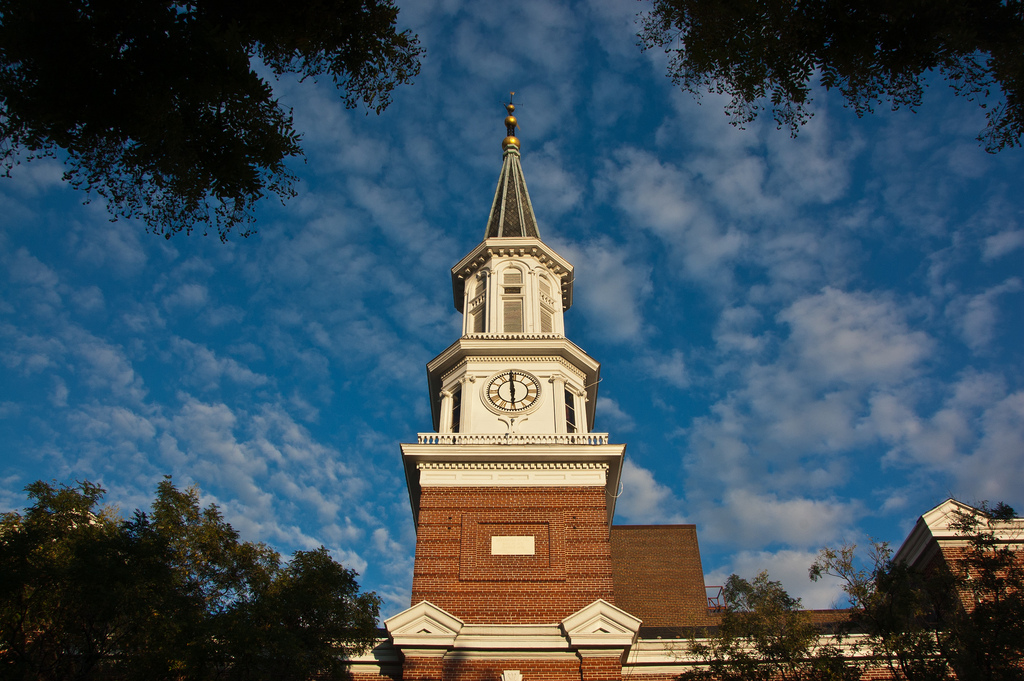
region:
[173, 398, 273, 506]
cloud is puffy in the sky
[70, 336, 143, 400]
cloud is puffy in the sky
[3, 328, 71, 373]
cloud is puffy in the sky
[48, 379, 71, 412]
cloud is puffy in the sky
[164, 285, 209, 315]
cloud is puffy in the sky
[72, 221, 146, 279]
cloud is puffy in the sky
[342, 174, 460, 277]
cloud is puffy in the sky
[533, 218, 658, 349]
cloud is puffy in the sky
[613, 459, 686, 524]
cloud is puffy in the sky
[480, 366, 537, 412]
the clock sitting on the side of the tower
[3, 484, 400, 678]
a green leafy tree next to the building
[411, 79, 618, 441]
a tower on top of the building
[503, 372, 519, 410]
the hands on the clock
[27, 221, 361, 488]
some more white clouds in the sky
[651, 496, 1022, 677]
another tree in front of the building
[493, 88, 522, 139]
the very top of the tower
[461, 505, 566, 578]
the sign in front of the building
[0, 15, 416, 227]
another tree branch higher up in the sky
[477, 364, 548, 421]
Clock on top of the tower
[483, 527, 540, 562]
white plaque on the wall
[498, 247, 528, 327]
window on top of the tower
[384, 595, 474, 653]
crown molding on the tower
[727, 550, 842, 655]
Tree growing in front of the tower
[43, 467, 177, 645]
Tree growing in front of the tower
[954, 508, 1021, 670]
Tree growing in front of the tower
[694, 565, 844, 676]
Tree growing in front of the tower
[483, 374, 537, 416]
white and brown clock on the top of the tower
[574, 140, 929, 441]
the sky is white and blue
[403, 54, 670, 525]
the tower is white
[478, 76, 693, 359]
the tower is pointy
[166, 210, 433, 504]
the clouds are thin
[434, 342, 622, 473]
the clock hands are black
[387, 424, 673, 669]
the bricks are red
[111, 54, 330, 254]
the trees are silhouetted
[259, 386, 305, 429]
A cloud in the sky.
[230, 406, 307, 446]
A cloud in the sky.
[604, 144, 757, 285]
A cloud in the sky.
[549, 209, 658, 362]
A cloud in the sky.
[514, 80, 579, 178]
A cloud in the sky.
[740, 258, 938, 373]
A cloud in the sky.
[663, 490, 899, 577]
A cloud in the sky.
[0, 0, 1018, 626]
the white clouds in the blue sky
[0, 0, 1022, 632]
the blue sky has white clouds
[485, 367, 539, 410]
the hands on the clock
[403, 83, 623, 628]
the clock on the tower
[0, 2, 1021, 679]
the trees near the clock tower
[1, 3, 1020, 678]
the blue sky above the clock tower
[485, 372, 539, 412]
the clock has roman numerals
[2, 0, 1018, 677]
the clouds and the clock tower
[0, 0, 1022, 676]
the blue sky above the trees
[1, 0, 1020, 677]
the leaves on the trees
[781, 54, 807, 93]
green leaves on the tree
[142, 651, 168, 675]
green leaves on the tree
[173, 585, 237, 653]
green leaves on the tree